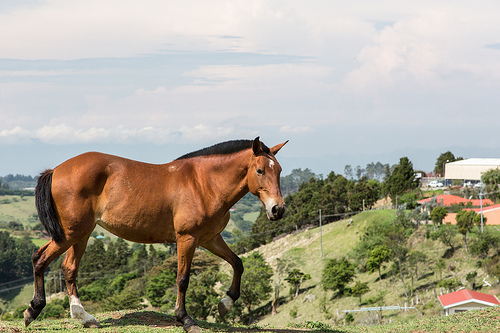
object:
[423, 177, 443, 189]
truck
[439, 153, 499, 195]
building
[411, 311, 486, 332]
ground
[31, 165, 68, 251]
tail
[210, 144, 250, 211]
neck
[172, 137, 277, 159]
black hair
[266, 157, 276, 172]
spot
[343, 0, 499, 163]
sky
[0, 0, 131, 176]
sky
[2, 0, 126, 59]
clouds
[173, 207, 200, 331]
leg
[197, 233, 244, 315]
leg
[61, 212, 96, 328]
leg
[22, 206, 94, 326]
leg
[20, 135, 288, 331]
horse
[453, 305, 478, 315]
wall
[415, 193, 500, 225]
house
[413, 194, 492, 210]
red roof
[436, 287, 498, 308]
red roof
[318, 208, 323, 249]
poles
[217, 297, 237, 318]
hoof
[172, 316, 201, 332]
hoof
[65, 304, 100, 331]
hoof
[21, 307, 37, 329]
hoof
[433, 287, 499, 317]
building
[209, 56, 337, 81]
clouds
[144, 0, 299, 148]
sky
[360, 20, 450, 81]
clouds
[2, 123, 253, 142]
clouds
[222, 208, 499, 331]
hill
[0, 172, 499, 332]
field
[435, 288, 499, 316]
house